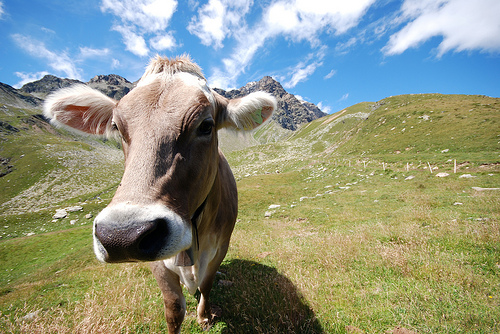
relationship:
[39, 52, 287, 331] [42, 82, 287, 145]
cow has ears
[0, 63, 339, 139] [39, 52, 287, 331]
mountains behind cow